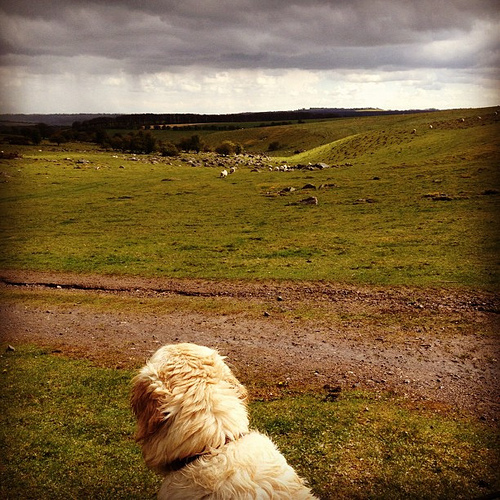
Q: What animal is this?
A: Dog.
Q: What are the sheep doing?
A: Grazing.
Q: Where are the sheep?
A: On FIELD.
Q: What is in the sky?
A: Clouds.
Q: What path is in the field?
A: Dirt.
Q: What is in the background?
A: Hills.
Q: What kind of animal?
A: Dog.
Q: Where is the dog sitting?
A: Grass.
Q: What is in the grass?
A: Stones.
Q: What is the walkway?
A: Dirt.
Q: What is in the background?
A: Mountains.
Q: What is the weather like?
A: Cloudy.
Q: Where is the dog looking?
A: Into the distance.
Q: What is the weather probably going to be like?
A: Stormy.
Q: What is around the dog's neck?
A: Collar.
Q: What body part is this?
A: Head.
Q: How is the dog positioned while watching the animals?
A: Sitting.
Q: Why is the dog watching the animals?
A: To protect.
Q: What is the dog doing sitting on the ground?
A: Watching the animals.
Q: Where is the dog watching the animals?
A: Field.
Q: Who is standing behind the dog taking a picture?
A: Herd and pet owner.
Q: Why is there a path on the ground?
A: Tracks from vehicles.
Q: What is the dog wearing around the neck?
A: Collar.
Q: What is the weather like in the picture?
A: Stormy clouds.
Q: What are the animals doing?
A: Grazing.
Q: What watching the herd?
A: A dog.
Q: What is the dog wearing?
A: Collar.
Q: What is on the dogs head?
A: Ears.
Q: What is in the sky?
A: Clouds.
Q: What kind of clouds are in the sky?
A: Rain.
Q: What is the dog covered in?
A: Fur.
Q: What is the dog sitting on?
A: Grass.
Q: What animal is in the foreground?
A: A dog.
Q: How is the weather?
A: Stormy.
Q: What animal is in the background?
A: Sheep.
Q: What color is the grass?
A: Green.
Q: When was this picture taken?
A: Daytime.